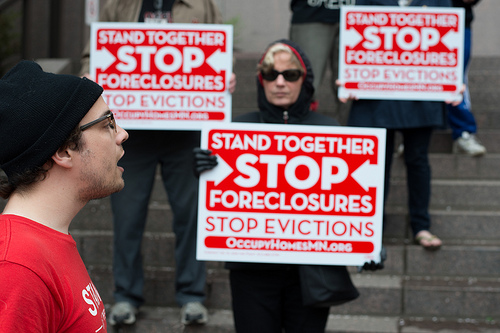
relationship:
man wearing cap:
[1, 53, 136, 332] [0, 55, 113, 194]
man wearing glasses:
[1, 53, 136, 332] [64, 101, 128, 145]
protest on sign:
[205, 151, 378, 240] [188, 115, 392, 273]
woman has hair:
[175, 31, 380, 332] [254, 37, 309, 83]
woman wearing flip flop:
[328, 1, 460, 256] [405, 221, 449, 255]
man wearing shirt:
[1, 53, 136, 332] [1, 208, 110, 332]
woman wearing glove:
[175, 31, 380, 332] [188, 135, 223, 179]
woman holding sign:
[175, 31, 380, 332] [188, 115, 392, 273]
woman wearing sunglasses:
[175, 31, 380, 332] [255, 62, 311, 88]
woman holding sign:
[328, 1, 460, 256] [329, 2, 473, 113]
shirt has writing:
[1, 208, 110, 332] [79, 278, 111, 332]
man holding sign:
[79, 1, 241, 332] [83, 18, 240, 146]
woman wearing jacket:
[175, 31, 380, 332] [197, 35, 367, 312]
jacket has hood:
[197, 35, 367, 312] [244, 32, 321, 123]